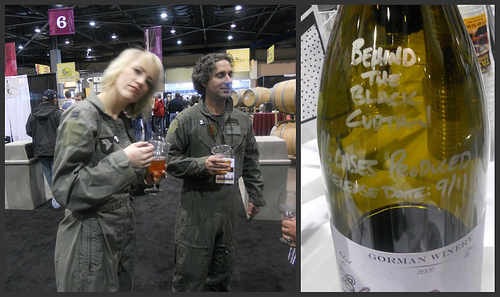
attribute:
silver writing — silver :
[341, 33, 487, 223]